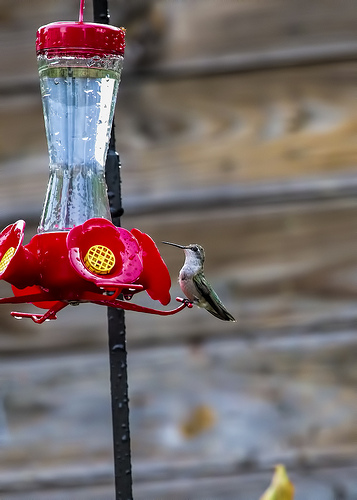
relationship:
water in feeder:
[61, 144, 100, 209] [2, 5, 204, 290]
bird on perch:
[160, 238, 236, 321] [101, 303, 190, 315]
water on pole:
[61, 144, 100, 209] [101, 332, 139, 499]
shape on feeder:
[69, 225, 142, 288] [2, 5, 204, 290]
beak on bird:
[153, 234, 190, 253] [185, 223, 246, 329]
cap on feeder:
[37, 21, 124, 66] [2, 5, 204, 290]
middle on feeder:
[85, 245, 115, 269] [2, 5, 204, 290]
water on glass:
[61, 144, 100, 209] [37, 61, 117, 221]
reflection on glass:
[91, 84, 108, 171] [37, 61, 117, 221]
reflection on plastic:
[91, 84, 108, 171] [39, 62, 122, 233]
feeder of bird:
[2, 5, 204, 290] [160, 238, 236, 321]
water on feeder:
[61, 144, 100, 209] [2, 5, 204, 290]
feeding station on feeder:
[125, 225, 184, 313] [2, 5, 204, 290]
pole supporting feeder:
[101, 332, 139, 499] [2, 5, 204, 290]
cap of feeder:
[37, 21, 124, 66] [2, 5, 204, 290]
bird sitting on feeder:
[160, 238, 236, 321] [2, 5, 204, 290]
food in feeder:
[57, 132, 96, 206] [2, 5, 204, 290]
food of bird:
[57, 132, 96, 206] [160, 238, 236, 321]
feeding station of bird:
[125, 225, 184, 313] [160, 238, 236, 321]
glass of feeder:
[37, 61, 117, 221] [2, 5, 204, 290]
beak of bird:
[153, 234, 190, 253] [160, 238, 236, 321]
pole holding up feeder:
[101, 332, 139, 499] [2, 5, 204, 290]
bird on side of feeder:
[160, 238, 236, 321] [2, 5, 204, 290]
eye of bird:
[192, 247, 197, 251] [160, 238, 236, 321]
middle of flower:
[81, 245, 124, 273] [69, 225, 142, 288]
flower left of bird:
[76, 216, 148, 292] [185, 223, 246, 329]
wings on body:
[194, 280, 225, 297] [180, 282, 244, 331]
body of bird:
[180, 282, 244, 331] [160, 238, 236, 321]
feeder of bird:
[2, 5, 204, 290] [185, 223, 246, 329]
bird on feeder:
[160, 238, 236, 321] [2, 5, 204, 290]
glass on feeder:
[37, 61, 117, 221] [2, 5, 204, 290]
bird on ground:
[256, 449, 297, 498] [6, 443, 342, 486]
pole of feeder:
[104, 312, 133, 500] [2, 5, 204, 290]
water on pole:
[114, 360, 135, 416] [104, 312, 133, 500]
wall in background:
[156, 54, 314, 196] [126, 20, 352, 337]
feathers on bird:
[172, 261, 196, 286] [160, 238, 236, 321]